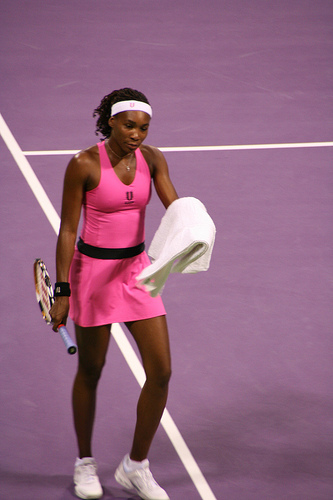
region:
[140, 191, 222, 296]
fluffy white towel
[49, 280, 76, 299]
black tennis wrist band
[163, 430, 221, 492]
solid white line on tennis court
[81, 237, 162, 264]
black belt around tennis dress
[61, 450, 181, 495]
pair of white sneakers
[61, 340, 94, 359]
black top of tennis racquet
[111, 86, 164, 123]
white tennis head band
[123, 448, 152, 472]
tiny white tennis socks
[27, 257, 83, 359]
multi colored tennis racquet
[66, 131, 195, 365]
pink tennis dress with black logo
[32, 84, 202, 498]
Girl on a tennis court.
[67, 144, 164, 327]
A girl wearing pink tennis outfit.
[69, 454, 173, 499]
Girl wearing white tennis shoes.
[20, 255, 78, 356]
Girl carrying a tennis racket.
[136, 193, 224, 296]
Girl carrying a white towel.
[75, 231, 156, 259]
Black ban around pink tennis outfit.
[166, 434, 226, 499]
White line on tennis court.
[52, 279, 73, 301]
Black ban around girl's wrist.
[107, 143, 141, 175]
Necklace around girl's neck.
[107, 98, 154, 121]
White ban around girl's head.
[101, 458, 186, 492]
heel lifted off ground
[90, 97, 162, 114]
white hairband with pink design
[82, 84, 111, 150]
loose curls extending from styled hair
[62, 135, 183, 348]
pink halter tennis dress with black band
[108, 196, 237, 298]
lower arm holding folded towel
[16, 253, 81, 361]
hand holding tennis racket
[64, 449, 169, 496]
white tennis shoes and white socks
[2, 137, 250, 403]
white lines dividing tennis court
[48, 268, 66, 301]
black wrist band with white design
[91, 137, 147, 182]
chain necklace with pendant around neck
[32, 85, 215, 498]
Tennis player is walking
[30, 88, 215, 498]
Tennis player with pink dress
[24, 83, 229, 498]
Tennis player carrying a racket in her right hand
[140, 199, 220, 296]
Folded white towel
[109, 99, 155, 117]
White headband on head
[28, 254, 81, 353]
Racket on hand of tennis player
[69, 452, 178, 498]
Pair of white tennis shoes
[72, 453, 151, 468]
White socks of tennis player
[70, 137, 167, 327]
Pink sleeveless dress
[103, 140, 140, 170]
Necklace on neck